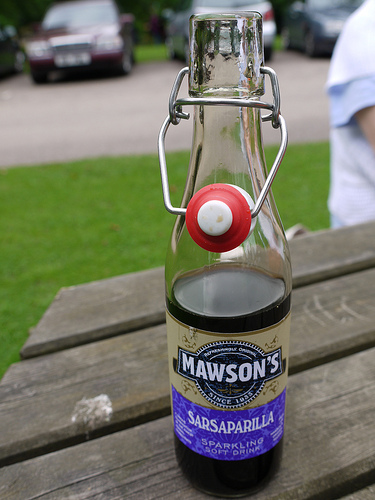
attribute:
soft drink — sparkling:
[155, 3, 295, 498]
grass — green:
[3, 159, 162, 270]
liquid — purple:
[164, 261, 292, 491]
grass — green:
[2, 136, 330, 373]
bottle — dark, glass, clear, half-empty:
[158, 6, 304, 492]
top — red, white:
[186, 181, 258, 251]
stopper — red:
[183, 181, 256, 253]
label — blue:
[157, 335, 300, 401]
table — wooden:
[1, 221, 373, 499]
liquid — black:
[164, 261, 288, 326]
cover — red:
[185, 182, 258, 254]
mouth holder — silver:
[157, 63, 288, 219]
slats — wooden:
[44, 328, 154, 496]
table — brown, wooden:
[290, 218, 354, 344]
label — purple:
[173, 387, 286, 460]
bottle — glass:
[131, 3, 289, 494]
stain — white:
[65, 388, 116, 436]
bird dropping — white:
[67, 390, 113, 443]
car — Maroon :
[20, 2, 145, 98]